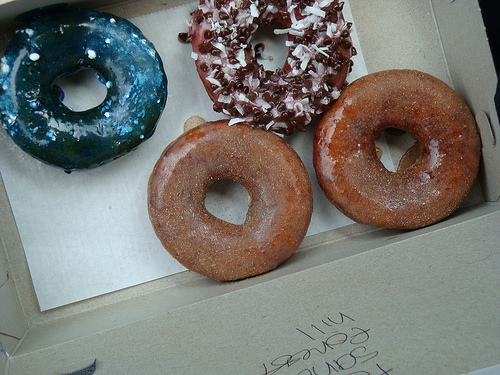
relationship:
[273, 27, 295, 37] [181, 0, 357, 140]
coconut on doughnut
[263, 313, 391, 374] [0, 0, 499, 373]
writing on box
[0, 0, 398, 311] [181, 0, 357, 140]
paper under doughnut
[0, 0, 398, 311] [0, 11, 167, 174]
paper under doughnut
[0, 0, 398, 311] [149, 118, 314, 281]
paper under doughnut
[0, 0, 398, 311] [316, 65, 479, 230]
paper under doughnut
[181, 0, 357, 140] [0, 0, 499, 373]
doughnut in box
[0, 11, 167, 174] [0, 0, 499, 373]
doughnut in box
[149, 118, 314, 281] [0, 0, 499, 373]
doughnut in box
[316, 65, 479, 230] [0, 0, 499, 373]
doughnut in box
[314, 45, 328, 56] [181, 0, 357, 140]
speck on doughnut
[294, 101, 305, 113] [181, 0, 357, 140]
speck on doughnut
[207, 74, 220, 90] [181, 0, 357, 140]
speck on doughnut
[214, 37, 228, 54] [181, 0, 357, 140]
speck on doughnut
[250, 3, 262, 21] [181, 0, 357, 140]
speck on doughnut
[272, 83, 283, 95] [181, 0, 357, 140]
piece of chocolate on doughnut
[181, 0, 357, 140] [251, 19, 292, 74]
doughnut has hole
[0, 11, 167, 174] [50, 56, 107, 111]
doughnut has hole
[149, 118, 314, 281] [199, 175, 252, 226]
doughnut has hole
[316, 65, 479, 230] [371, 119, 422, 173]
doughnut has hole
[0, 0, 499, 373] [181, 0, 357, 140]
box with doughnut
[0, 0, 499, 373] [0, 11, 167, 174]
box with doughnut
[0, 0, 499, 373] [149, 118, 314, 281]
box with doughnut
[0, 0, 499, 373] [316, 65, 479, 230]
box with doughnut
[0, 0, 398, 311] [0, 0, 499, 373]
paper in box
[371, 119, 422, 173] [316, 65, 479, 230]
hole in doughnut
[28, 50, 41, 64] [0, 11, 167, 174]
sprinkle on doughnut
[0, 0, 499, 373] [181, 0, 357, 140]
box has doughnut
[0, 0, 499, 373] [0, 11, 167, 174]
box has doughnut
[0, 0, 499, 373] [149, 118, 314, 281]
box has doughnut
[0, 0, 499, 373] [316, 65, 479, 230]
box has doughnut